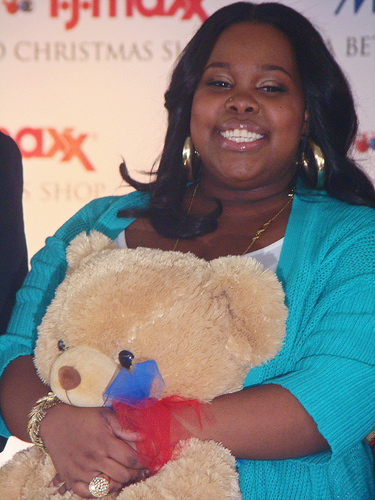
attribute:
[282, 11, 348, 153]
hair — black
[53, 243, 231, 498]
teddy bear — brown, large, stuffed, tan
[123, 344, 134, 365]
eye — brown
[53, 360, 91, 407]
nose — brown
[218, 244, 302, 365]
ear — brown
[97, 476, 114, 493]
ring — large, round, cocktail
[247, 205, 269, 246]
necklace — golden, gold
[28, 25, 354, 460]
lady — young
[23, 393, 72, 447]
bracelet — gold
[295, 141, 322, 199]
earrings — gold, hoop, large, group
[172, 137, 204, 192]
earring — large, gold, one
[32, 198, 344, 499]
jacket — turquoise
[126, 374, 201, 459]
ribbon — red, blue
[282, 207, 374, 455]
sweater — blue, turquoise, knot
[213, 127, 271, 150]
teeth — smile, several, white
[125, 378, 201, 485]
net — red, blue, tied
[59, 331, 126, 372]
eyes — black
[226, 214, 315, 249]
chain — gold